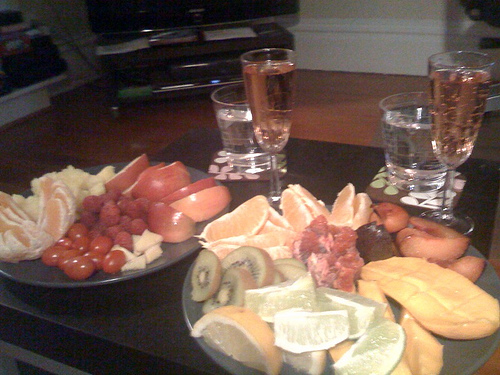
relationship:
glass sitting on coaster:
[211, 81, 272, 166] [207, 147, 287, 181]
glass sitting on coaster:
[380, 87, 447, 193] [364, 160, 466, 212]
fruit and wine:
[27, 170, 229, 272] [240, 45, 301, 202]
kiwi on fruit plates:
[188, 247, 308, 312] [180, 203, 500, 374]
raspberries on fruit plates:
[80, 190, 151, 248] [0, 161, 231, 289]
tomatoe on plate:
[89, 235, 114, 255] [3, 140, 242, 292]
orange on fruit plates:
[192, 182, 375, 262] [0, 161, 231, 289]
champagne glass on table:
[421, 47, 496, 240] [0, 61, 497, 373]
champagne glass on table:
[238, 47, 300, 202] [0, 61, 497, 373]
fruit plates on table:
[180, 203, 500, 374] [6, 120, 494, 374]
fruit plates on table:
[0, 161, 231, 289] [6, 120, 494, 374]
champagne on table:
[238, 62, 298, 156] [6, 120, 494, 374]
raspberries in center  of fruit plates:
[302, 207, 379, 307] [180, 203, 500, 374]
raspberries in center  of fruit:
[302, 207, 379, 307] [209, 182, 431, 359]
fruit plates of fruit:
[180, 203, 500, 374] [209, 182, 431, 359]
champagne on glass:
[247, 63, 302, 152] [235, 45, 337, 240]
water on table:
[201, 57, 323, 189] [297, 141, 359, 208]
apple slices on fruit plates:
[108, 155, 199, 192] [0, 157, 231, 289]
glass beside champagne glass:
[211, 83, 277, 174] [238, 47, 299, 212]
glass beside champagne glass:
[377, 91, 456, 194] [418, 50, 495, 239]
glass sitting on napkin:
[377, 91, 456, 194] [367, 148, 472, 223]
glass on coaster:
[377, 91, 456, 194] [366, 164, 466, 213]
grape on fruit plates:
[103, 249, 124, 271] [0, 161, 231, 289]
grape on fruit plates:
[64, 255, 91, 280] [0, 161, 231, 289]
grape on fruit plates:
[42, 242, 65, 266] [0, 161, 231, 289]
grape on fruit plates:
[68, 220, 85, 238] [0, 161, 231, 289]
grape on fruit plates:
[88, 232, 112, 253] [0, 161, 231, 289]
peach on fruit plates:
[370, 202, 486, 284] [180, 197, 499, 372]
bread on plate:
[350, 267, 479, 338] [182, 246, 499, 374]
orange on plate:
[192, 182, 375, 262] [142, 146, 487, 373]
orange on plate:
[192, 182, 375, 262] [182, 204, 497, 374]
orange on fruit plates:
[211, 196, 266, 241] [180, 203, 500, 374]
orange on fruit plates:
[192, 182, 375, 262] [180, 203, 500, 374]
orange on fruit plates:
[34, 189, 69, 230] [180, 203, 500, 374]